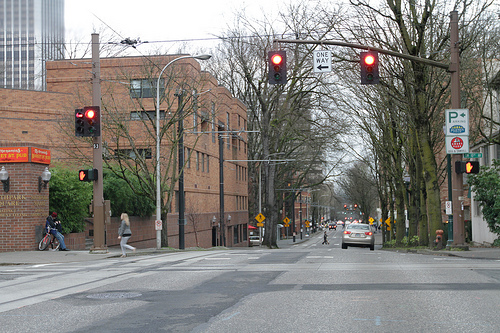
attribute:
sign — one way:
[312, 47, 333, 75]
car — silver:
[332, 210, 385, 265]